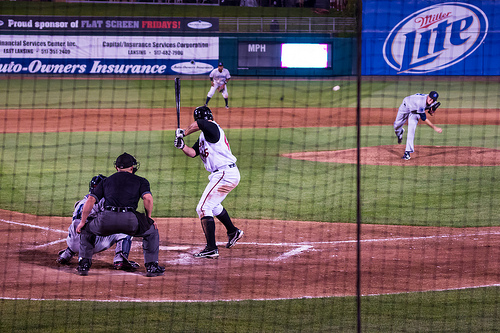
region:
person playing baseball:
[165, 67, 256, 264]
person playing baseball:
[395, 76, 437, 157]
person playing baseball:
[204, 59, 234, 104]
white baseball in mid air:
[331, 77, 344, 97]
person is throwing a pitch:
[388, 80, 442, 162]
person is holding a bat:
[166, 77, 280, 282]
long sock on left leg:
[196, 214, 220, 250]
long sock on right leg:
[216, 201, 246, 232]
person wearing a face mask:
[107, 145, 139, 173]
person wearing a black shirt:
[91, 160, 153, 212]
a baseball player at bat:
[172, 75, 246, 260]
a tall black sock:
[198, 215, 218, 251]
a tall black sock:
[214, 208, 234, 237]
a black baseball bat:
[172, 75, 183, 148]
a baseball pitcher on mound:
[394, 91, 444, 161]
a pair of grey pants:
[75, 207, 160, 264]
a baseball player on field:
[202, 60, 232, 107]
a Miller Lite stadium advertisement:
[362, 3, 498, 75]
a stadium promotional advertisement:
[0, 33, 218, 78]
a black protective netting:
[2, 1, 497, 328]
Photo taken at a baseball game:
[5, 7, 485, 323]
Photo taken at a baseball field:
[9, 6, 491, 328]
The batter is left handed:
[187, 101, 241, 262]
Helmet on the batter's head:
[191, 103, 214, 121]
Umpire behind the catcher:
[76, 147, 171, 269]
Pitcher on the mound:
[388, 81, 456, 166]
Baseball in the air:
[329, 82, 346, 97]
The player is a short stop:
[204, 58, 239, 110]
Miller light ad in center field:
[362, 3, 497, 80]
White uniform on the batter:
[184, 116, 259, 260]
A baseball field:
[0, 76, 499, 332]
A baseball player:
[173, 103, 243, 258]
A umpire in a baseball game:
[74, 153, 164, 277]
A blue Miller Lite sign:
[361, 1, 498, 76]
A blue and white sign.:
[0, 33, 221, 73]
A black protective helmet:
[193, 104, 213, 121]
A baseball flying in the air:
[332, 83, 339, 90]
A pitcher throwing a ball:
[393, 90, 442, 160]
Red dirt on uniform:
[207, 182, 236, 197]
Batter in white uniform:
[158, 68, 263, 260]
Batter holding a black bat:
[164, 67, 194, 164]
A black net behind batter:
[36, 25, 456, 295]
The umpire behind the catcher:
[93, 144, 164, 279]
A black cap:
[103, 149, 153, 173]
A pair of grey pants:
[88, 208, 162, 272]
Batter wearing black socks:
[182, 210, 268, 253]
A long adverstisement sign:
[14, 27, 259, 77]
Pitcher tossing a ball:
[388, 69, 451, 170]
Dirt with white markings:
[173, 220, 320, 283]